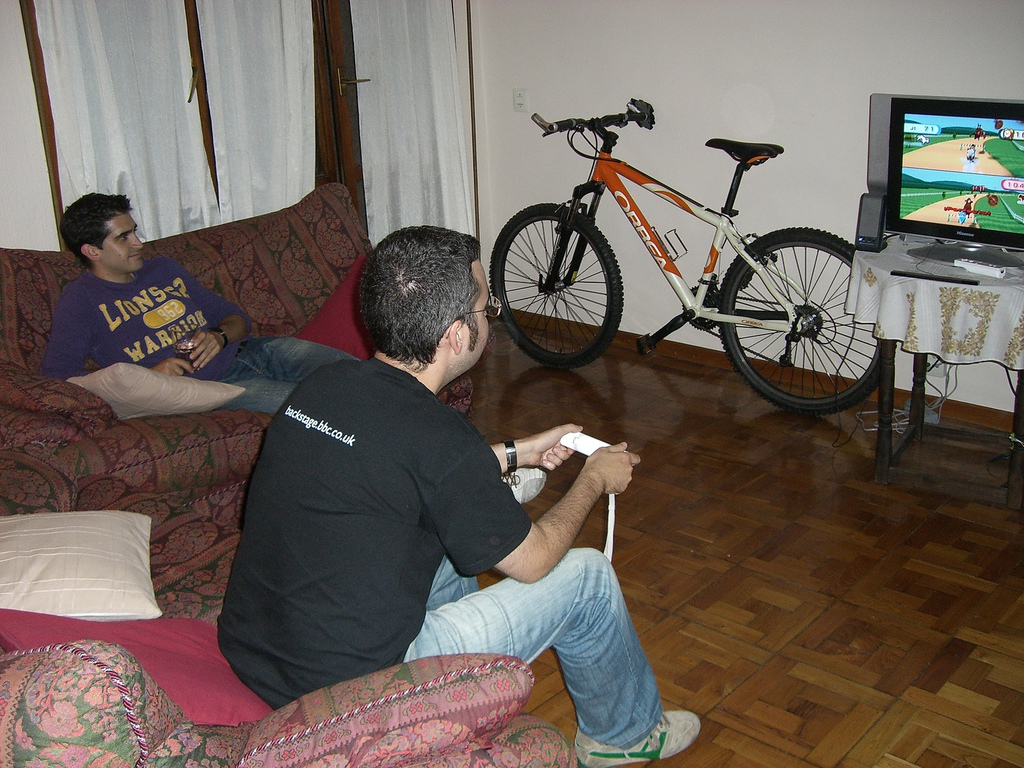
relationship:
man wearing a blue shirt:
[38, 190, 358, 412] [45, 263, 236, 375]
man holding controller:
[216, 219, 722, 761] [551, 427, 635, 558]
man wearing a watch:
[216, 219, 722, 761] [497, 436, 532, 481]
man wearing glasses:
[216, 219, 722, 761] [455, 286, 509, 321]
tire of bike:
[484, 199, 631, 365] [480, 99, 902, 417]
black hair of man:
[356, 224, 480, 371] [216, 219, 722, 761]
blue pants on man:
[415, 539, 682, 737] [216, 219, 722, 761]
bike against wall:
[483, 92, 880, 429] [464, 0, 1022, 428]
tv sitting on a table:
[859, 87, 1022, 262] [875, 259, 1022, 468]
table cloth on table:
[841, 244, 1022, 365] [819, 241, 1022, 444]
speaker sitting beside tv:
[853, 184, 898, 251] [864, 80, 1021, 251]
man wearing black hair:
[216, 219, 722, 761] [345, 225, 495, 368]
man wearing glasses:
[216, 219, 722, 761] [455, 297, 503, 316]